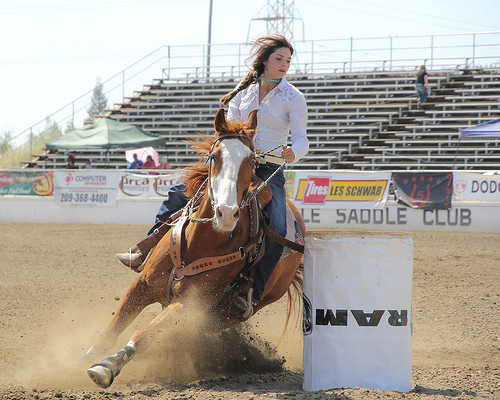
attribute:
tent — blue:
[458, 115, 498, 145]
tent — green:
[44, 113, 172, 170]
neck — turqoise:
[256, 76, 281, 89]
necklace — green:
[255, 76, 280, 83]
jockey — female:
[123, 39, 317, 315]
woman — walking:
[413, 61, 432, 108]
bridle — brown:
[164, 210, 264, 293]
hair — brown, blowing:
[220, 31, 295, 103]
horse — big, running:
[72, 107, 307, 392]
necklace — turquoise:
[252, 75, 280, 84]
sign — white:
[294, 229, 420, 395]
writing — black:
[311, 302, 408, 333]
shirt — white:
[233, 79, 305, 151]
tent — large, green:
[50, 117, 167, 179]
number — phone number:
[59, 189, 109, 203]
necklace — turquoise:
[227, 67, 291, 98]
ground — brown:
[1, 206, 496, 398]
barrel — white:
[300, 231, 418, 397]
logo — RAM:
[300, 296, 409, 336]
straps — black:
[90, 347, 134, 387]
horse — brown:
[74, 95, 304, 367]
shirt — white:
[414, 69, 430, 88]